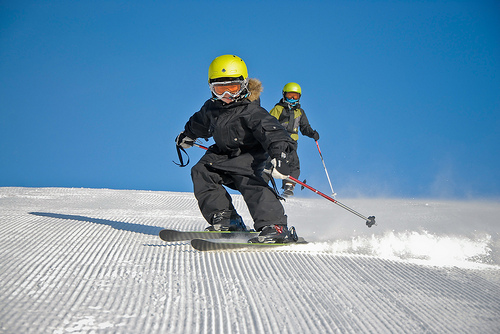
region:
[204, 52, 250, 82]
a yellow helmet on a skier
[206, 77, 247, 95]
white rimmed goggles on a skier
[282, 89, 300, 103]
blue rimmed goggles on a skier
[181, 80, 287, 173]
a black coat with a fur trimmed hood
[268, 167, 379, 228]
a red and silver ski pole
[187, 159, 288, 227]
black pants on a skier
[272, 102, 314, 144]
a black and yellow coat on a skier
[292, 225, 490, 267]
snow spraying up behind a skier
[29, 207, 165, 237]
the shadow of a skier on the snow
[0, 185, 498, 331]
a snowy white slope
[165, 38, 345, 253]
two people skiing down the mountainside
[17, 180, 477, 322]
lines in the snow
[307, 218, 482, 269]
snow dust kicked up by skier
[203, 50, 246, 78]
yellow helmet of skier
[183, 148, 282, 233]
black pants of skier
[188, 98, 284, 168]
black coat of skier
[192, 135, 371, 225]
gray and red ski poles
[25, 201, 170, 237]
shadow of the skier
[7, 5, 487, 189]
clear blue sky above the mountain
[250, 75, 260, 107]
fur lining of coat hood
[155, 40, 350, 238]
child snowboarding down hill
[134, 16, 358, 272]
the snow has been made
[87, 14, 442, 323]
spray off of fresh snow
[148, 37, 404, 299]
the helmet is yellow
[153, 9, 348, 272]
the jacket is black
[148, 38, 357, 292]
the family is sking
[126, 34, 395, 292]
the sky is clear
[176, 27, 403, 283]
he wears orange goggles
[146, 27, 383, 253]
the skis are black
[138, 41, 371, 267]
the coat has a fur hood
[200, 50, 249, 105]
a child's snowboard helmet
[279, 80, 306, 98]
a neon colored helmet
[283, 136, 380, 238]
a few red ski poles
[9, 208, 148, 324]
some groomed snow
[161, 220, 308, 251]
a short set of skiis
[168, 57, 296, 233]
a black ski outfit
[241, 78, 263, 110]
a fur lined hood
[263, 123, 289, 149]
a black pocket on a sleeve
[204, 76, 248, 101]
a pair of ski goggles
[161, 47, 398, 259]
a pair of kids downhill skiing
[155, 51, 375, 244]
Two children skiing.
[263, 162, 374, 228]
A child holding a ski pole.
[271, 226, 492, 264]
Snow being kicked up by the skis.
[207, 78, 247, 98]
Child is wearing goggles.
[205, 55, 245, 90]
The child is wearing a yellow helmet.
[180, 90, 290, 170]
The child is wearing a black coat.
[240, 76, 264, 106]
Fur around the hood of the coat.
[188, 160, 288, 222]
The child is wearing black snow pants.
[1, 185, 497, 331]
Ridges throughout the snow.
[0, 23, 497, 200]
Deep blue sky above.